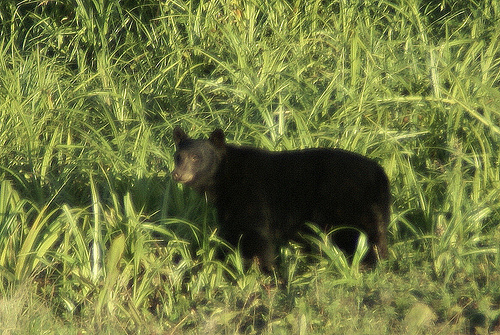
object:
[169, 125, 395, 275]
bear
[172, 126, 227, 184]
head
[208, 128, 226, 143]
ear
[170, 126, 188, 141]
ear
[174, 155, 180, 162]
eyes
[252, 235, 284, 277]
leg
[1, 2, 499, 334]
grass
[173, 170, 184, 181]
nose